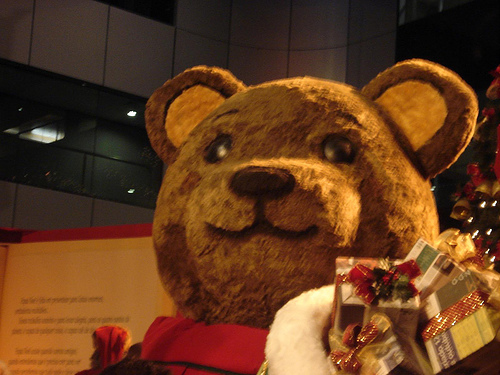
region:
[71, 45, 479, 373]
brown teddy bear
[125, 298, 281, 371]
red collar on teddy bear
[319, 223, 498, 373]
boxed gifts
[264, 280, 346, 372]
top of white stocking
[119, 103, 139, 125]
round white ceiling lamp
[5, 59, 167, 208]
round reflective windows on side of building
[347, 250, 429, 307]
red bow on top of gift boxes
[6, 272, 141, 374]
writing on side of wooden wall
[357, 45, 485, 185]
brown teddy bear ear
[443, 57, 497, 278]
christmas tree behind teddy bear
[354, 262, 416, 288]
a red bow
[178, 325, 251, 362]
a bow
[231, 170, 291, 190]
nose of the teddybear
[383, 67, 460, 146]
left ear of the teddy bear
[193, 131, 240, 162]
right eye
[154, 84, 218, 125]
right ear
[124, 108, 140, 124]
a light in the ceiling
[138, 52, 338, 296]
a brown bear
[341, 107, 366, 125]
eyebrow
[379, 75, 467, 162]
the bears ear is brown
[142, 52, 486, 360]
a huge teddy bear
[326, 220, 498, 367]
a bag of christmas presents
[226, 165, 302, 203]
a brown bear nose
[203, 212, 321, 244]
a brown bear mouth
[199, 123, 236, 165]
a brown bear eye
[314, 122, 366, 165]
a brown bear eye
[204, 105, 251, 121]
a brown bear eye brow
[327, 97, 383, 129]
a brown bear eye brow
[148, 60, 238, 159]
a brown bear ear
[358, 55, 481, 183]
a brown bear ear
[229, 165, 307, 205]
The teddy bear nose.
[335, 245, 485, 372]
A collection of gifts.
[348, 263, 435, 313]
The red bow on the gift.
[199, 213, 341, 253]
The bears mouth.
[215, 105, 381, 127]
The stuffed bears eyebrows.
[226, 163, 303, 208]
The bears nose.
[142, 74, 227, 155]
The bears ear.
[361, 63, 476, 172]
The bears left ear.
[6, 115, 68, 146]
The light in the ceiling.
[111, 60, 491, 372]
The large stuffed bear.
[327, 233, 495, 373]
Boxes of christmas gifts wrapped.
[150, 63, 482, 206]
The bears eyes,ears,and nose.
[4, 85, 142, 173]
Ceiling lights turned on.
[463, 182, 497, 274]
Lit christmas tree lights.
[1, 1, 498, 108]
White tiles on wall.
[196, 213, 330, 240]
The teddy bears mouth.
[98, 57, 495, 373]
A christmas teddy bear with gifts.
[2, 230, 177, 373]
White paper with writing.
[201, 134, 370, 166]
Two black eyes.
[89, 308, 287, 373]
The bear's red clothes.